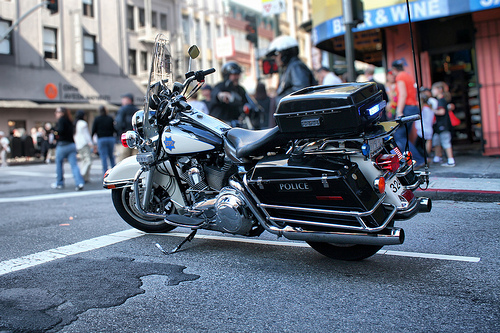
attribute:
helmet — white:
[265, 35, 300, 63]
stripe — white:
[10, 206, 101, 283]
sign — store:
[308, 0, 496, 48]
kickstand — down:
[151, 227, 200, 259]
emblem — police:
[163, 133, 177, 151]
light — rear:
[368, 151, 400, 175]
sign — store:
[292, 0, 497, 50]